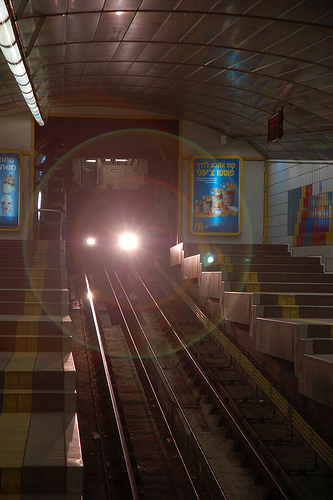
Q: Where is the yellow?
A: On the steps.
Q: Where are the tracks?
A: On the ground.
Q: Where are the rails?
A: On the ground.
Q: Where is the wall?
A: On the right.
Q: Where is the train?
A: On the tracks.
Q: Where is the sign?
A: On the wall.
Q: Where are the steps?
A: Next to the tracks.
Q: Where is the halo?
A: Around the light.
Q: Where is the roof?
A: Above the room.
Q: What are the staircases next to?
A: Train tracks.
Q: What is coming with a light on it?
A: Train.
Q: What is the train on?
A: Train tracks.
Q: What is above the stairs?
A: Rounded roof.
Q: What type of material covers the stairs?
A: Tiles.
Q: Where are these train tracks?
A: Underground.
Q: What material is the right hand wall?
A: Tiles.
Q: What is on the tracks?
A: A train.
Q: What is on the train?
A: A light.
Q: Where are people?
A: None in photo.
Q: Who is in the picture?
A: No one.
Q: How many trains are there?
A: One.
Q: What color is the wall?
A: White.